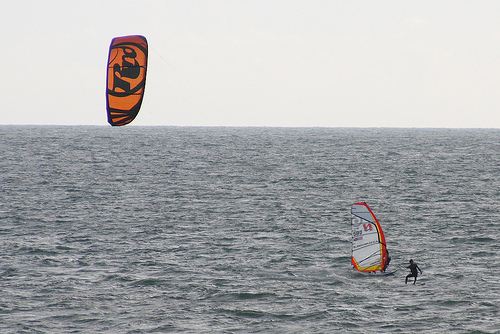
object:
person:
[403, 258, 422, 283]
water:
[1, 125, 499, 332]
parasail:
[107, 34, 149, 126]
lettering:
[111, 45, 137, 59]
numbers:
[361, 223, 369, 231]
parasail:
[350, 202, 388, 271]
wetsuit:
[402, 262, 420, 283]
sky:
[1, 0, 499, 128]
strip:
[359, 262, 383, 271]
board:
[354, 269, 398, 276]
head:
[408, 258, 413, 262]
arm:
[415, 262, 423, 271]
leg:
[405, 271, 412, 282]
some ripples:
[2, 126, 498, 333]